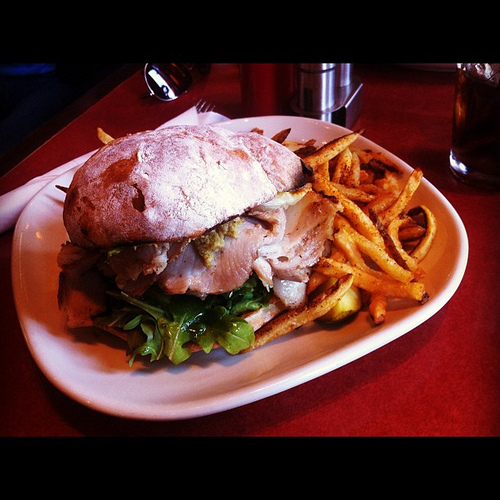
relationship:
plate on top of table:
[13, 113, 473, 424] [1, 65, 500, 436]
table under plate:
[1, 65, 500, 436] [13, 113, 473, 424]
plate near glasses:
[13, 113, 473, 424] [138, 63, 212, 101]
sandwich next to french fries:
[62, 124, 336, 368] [242, 124, 438, 354]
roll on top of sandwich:
[61, 126, 309, 245] [62, 124, 336, 368]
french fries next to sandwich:
[242, 124, 438, 354] [62, 124, 336, 368]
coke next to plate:
[447, 63, 498, 191] [13, 113, 473, 424]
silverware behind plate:
[1, 99, 231, 236] [13, 113, 473, 424]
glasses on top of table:
[138, 63, 212, 101] [1, 65, 500, 436]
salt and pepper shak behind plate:
[285, 64, 363, 130] [13, 113, 473, 424]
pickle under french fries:
[309, 277, 363, 328] [242, 124, 438, 354]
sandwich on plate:
[62, 124, 336, 368] [13, 113, 473, 424]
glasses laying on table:
[138, 63, 212, 101] [1, 65, 500, 436]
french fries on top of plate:
[242, 124, 438, 354] [13, 113, 473, 424]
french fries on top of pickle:
[242, 124, 438, 354] [309, 277, 363, 328]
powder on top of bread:
[128, 139, 241, 212] [63, 124, 313, 243]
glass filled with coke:
[449, 63, 499, 191] [447, 63, 498, 191]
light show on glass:
[451, 157, 467, 176] [449, 63, 499, 191]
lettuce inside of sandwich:
[93, 279, 273, 367] [62, 124, 336, 368]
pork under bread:
[151, 185, 339, 298] [63, 124, 313, 243]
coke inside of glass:
[447, 63, 498, 191] [449, 63, 499, 191]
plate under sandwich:
[13, 113, 473, 424] [62, 124, 336, 368]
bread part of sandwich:
[63, 124, 313, 243] [62, 124, 336, 368]